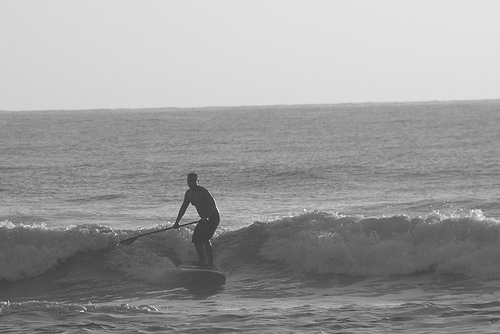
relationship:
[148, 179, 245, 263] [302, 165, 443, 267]
man in water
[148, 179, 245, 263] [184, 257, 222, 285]
man on surboard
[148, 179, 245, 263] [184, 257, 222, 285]
man in surboard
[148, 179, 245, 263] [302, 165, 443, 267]
man on water